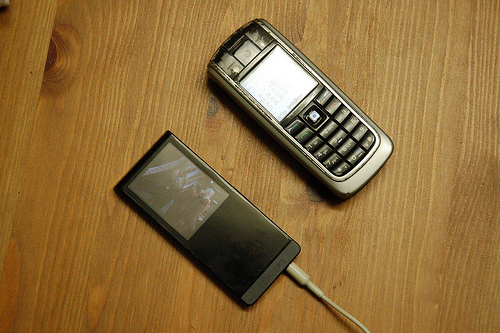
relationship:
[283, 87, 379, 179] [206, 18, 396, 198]
keyboard of electronic devices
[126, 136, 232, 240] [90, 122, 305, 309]
screen of ipod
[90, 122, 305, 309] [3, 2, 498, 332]
ipod laying on table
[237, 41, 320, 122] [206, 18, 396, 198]
screen of electronic devices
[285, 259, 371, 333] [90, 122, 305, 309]
charger of ipod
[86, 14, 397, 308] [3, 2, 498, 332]
electronic devices across table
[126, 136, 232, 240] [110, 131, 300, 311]
screen on ipod